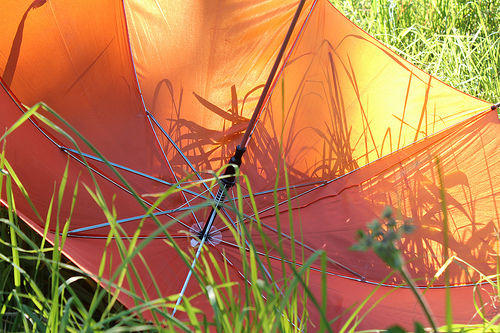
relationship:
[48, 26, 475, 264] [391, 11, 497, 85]
umbrella on grass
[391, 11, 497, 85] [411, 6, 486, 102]
grass not mowed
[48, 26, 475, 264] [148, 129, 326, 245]
umbrella has spokes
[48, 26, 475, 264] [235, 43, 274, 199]
umbrella has handle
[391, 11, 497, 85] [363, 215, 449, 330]
grass has wildflower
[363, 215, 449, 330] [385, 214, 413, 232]
wildflower has buds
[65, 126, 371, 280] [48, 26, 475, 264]
wires in umbrella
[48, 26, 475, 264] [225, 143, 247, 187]
umbrella has stem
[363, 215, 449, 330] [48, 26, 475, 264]
flower beside umbrella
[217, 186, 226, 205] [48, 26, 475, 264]
spring on umbrella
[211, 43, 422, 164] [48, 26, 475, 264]
shadow on umbrella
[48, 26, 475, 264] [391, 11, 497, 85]
umbrella lays on grass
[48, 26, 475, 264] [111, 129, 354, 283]
umbrella has spokes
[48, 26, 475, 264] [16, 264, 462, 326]
umbrella has fall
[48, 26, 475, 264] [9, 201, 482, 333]
umbrella on ground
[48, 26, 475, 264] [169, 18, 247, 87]
umbrella has fabric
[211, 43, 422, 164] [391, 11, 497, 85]
shadow of grass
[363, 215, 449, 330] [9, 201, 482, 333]
plant in ground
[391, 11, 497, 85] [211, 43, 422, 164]
grass has shadow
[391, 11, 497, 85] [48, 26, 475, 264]
grass surrounds umbrella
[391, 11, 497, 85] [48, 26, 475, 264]
grass behind umbrella